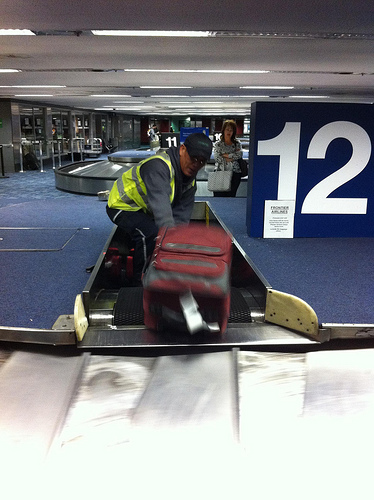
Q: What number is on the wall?
A: Twelve.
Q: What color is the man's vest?
A: Yellow.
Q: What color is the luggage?
A: Red.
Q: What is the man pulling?
A: Luggage.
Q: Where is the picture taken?
A: Airport.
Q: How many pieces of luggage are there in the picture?
A: One.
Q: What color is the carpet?
A: Blue.